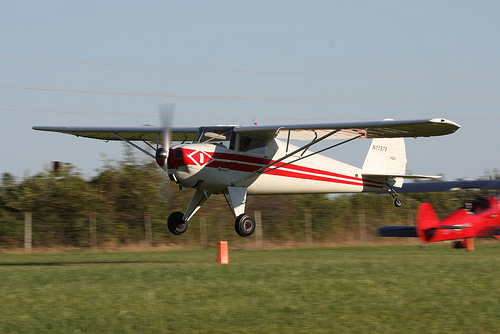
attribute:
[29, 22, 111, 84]
clouds — white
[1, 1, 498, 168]
sky — blue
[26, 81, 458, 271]
plane — red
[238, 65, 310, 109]
clouds — white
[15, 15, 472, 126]
sky — blue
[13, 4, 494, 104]
sky — blue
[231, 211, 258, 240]
tire — black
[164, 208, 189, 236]
tire — black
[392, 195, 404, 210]
tire — black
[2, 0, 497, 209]
sky — blue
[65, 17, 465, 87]
skies — clear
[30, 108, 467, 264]
plane — red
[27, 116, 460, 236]
airplane — preparing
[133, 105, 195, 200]
propeller — spinning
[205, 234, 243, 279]
cone — orange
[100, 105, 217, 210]
propeller — spinning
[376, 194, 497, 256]
plane — red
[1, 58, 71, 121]
clouds — white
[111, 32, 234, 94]
clouds — white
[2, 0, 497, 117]
sky — blue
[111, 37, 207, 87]
clouds — white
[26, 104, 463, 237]
plane — red, white